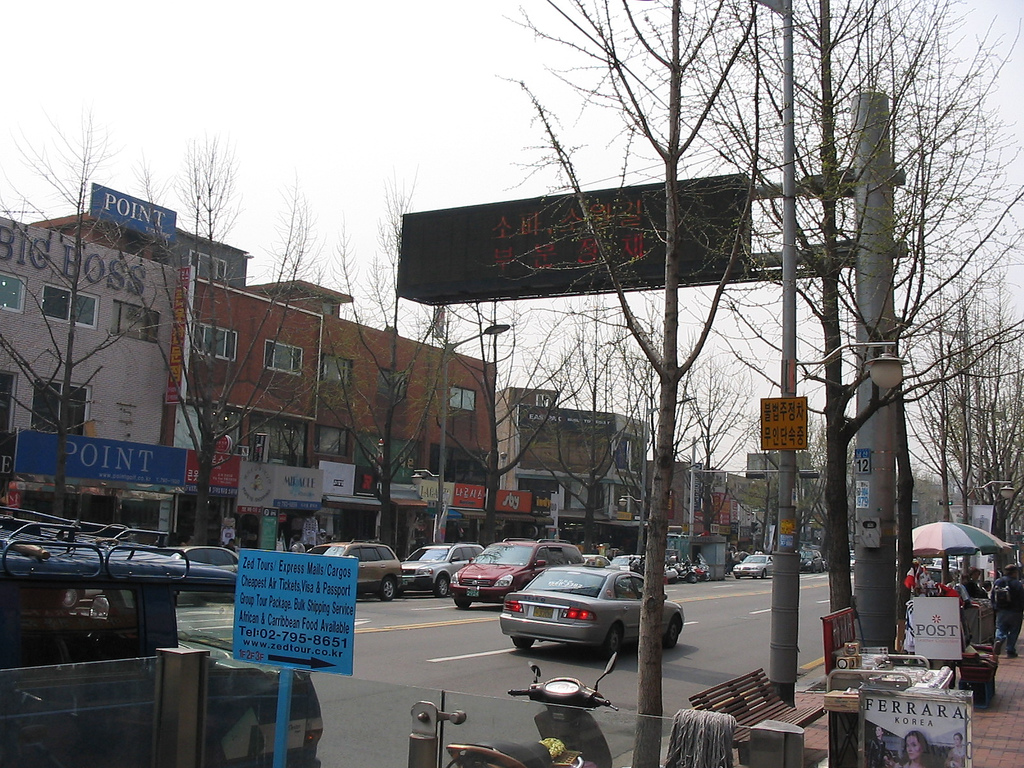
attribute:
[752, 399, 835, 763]
pole — tall, silver, metal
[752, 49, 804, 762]
light — street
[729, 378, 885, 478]
sign — orange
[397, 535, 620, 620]
van — red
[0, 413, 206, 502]
blue sign — blue 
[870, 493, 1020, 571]
umbrella — multi colored